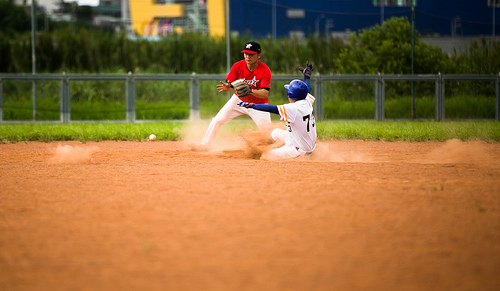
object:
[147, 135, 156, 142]
ball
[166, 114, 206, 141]
dust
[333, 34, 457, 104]
bushes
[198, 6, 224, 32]
part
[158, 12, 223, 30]
building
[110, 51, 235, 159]
mid air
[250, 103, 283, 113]
arm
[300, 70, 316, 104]
arm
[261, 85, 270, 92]
sleeve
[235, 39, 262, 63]
cap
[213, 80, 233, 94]
hand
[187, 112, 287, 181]
base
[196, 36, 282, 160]
baseman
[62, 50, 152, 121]
wall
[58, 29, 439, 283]
outfield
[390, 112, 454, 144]
grass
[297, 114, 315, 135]
numbers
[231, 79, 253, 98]
glove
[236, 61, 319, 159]
man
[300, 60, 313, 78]
glove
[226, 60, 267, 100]
jersey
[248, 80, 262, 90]
letters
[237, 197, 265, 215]
dirt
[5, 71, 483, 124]
fence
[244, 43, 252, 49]
logo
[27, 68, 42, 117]
pole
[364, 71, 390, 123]
pole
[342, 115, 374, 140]
grass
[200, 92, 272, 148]
pants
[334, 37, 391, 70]
hedge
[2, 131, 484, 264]
field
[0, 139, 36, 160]
dirt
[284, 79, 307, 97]
baseball helmet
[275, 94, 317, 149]
baseball jersey